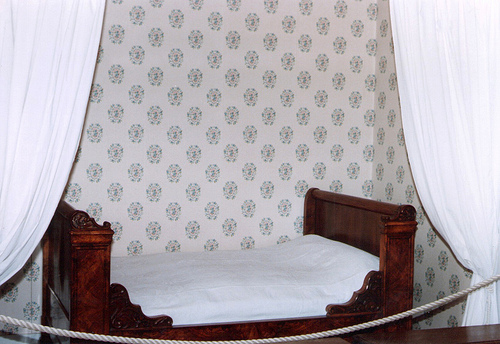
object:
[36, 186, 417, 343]
furniture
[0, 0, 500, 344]
wallpaper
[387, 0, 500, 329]
curtain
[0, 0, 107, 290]
curtain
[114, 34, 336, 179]
designs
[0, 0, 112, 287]
cloth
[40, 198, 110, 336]
footboard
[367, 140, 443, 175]
ground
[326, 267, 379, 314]
wooden piece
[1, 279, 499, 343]
rope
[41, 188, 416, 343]
bed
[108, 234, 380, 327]
sheet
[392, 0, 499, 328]
drape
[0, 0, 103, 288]
drape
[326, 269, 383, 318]
carving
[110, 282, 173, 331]
carving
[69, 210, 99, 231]
carving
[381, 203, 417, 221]
carving